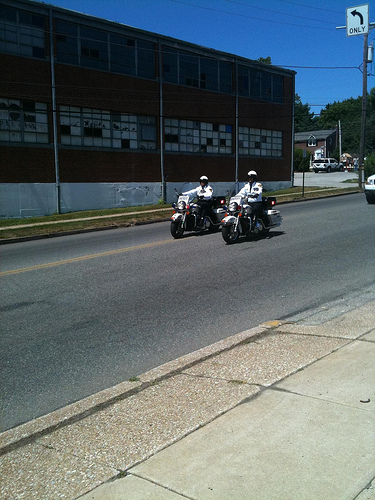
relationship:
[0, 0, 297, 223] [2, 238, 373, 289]
building near road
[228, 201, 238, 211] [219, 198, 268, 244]
headlight on bike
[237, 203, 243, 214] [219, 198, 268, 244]
indicator on bike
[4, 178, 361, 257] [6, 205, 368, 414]
curb on road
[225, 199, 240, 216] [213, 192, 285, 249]
headlight on motorcycle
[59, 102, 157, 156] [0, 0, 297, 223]
windows on building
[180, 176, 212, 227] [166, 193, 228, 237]
cop on motorcycle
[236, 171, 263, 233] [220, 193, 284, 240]
cop on motorcycle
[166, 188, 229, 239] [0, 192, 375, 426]
motorcycle on road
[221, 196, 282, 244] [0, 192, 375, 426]
bike on road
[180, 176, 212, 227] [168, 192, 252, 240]
cop riding motorcycles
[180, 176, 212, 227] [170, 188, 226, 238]
cop on motorcycle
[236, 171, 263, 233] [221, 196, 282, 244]
cop on bike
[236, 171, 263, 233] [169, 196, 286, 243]
cop riding motorcycles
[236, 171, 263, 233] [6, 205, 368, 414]
cop on road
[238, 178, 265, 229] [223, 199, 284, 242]
cop on motorcycle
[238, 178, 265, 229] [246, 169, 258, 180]
cop with helmet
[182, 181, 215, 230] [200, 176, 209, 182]
cop with helmet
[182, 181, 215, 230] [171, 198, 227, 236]
cop on motorcycle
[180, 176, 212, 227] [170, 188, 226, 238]
cop riding motorcycle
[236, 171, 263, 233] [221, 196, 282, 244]
cop riding bike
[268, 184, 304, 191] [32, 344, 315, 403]
grass on sidewalk curb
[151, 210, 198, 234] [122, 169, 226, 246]
wheel of motorcycle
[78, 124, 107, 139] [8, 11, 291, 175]
windows on building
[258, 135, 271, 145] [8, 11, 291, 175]
windows on building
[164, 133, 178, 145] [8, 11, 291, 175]
windows on building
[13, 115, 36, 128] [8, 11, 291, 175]
windows on building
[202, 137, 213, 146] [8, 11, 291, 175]
windows on building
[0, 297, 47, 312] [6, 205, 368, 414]
stain on road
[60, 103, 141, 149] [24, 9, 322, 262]
window on building